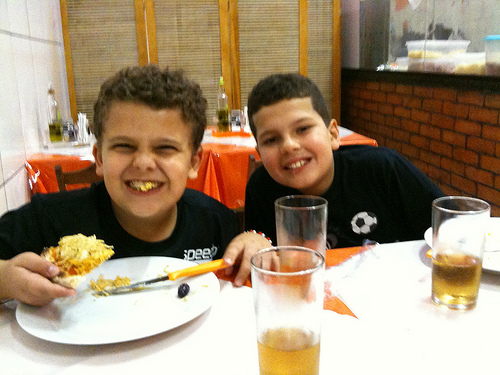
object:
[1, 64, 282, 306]
boys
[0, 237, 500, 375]
table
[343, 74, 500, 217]
wall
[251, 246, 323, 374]
glass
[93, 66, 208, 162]
hair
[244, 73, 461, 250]
boy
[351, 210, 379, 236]
ball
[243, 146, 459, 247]
shirt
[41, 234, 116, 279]
food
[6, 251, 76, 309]
hand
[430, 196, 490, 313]
glasses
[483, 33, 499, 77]
container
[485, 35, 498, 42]
lid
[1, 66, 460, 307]
kids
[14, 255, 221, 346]
plate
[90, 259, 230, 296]
knife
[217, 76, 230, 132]
bottle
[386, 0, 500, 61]
window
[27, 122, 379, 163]
table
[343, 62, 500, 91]
table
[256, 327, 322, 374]
juice